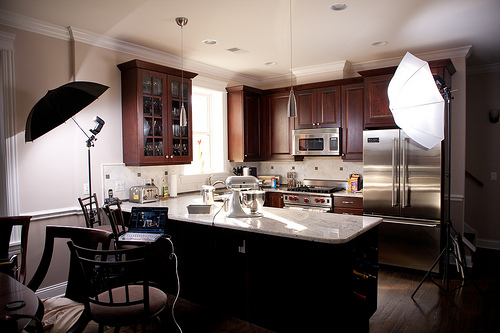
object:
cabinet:
[116, 54, 500, 168]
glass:
[143, 78, 192, 158]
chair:
[68, 238, 170, 332]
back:
[71, 239, 155, 319]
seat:
[90, 278, 170, 323]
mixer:
[221, 172, 268, 220]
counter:
[110, 190, 385, 244]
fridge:
[358, 126, 451, 276]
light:
[175, 13, 195, 127]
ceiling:
[0, 4, 499, 87]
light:
[285, 1, 300, 117]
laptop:
[119, 204, 173, 244]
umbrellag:
[382, 44, 477, 305]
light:
[19, 89, 229, 209]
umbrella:
[21, 77, 111, 224]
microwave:
[290, 125, 340, 154]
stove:
[282, 175, 346, 205]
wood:
[228, 58, 457, 164]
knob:
[164, 153, 169, 157]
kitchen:
[7, 1, 497, 326]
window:
[144, 76, 164, 153]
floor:
[76, 243, 499, 330]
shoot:
[8, 1, 495, 331]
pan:
[188, 203, 212, 214]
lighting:
[386, 51, 475, 309]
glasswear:
[171, 123, 188, 138]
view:
[185, 87, 225, 176]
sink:
[207, 176, 240, 198]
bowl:
[238, 188, 269, 210]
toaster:
[127, 182, 161, 204]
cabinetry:
[119, 54, 458, 166]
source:
[21, 76, 113, 269]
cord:
[210, 195, 227, 232]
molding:
[0, 7, 476, 93]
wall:
[15, 29, 235, 281]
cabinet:
[241, 245, 338, 322]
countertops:
[120, 190, 383, 246]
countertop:
[115, 182, 386, 233]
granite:
[114, 189, 381, 247]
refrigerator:
[358, 131, 442, 269]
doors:
[361, 129, 401, 219]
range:
[284, 175, 354, 208]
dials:
[286, 194, 331, 202]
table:
[3, 267, 43, 328]